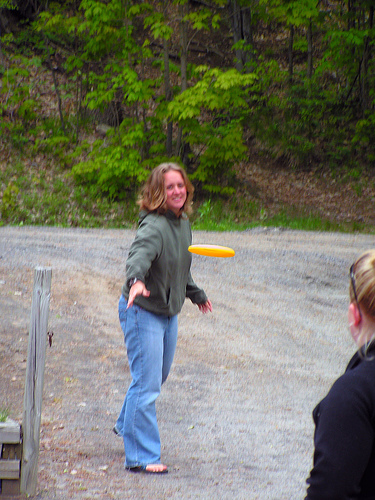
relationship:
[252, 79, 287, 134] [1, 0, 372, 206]
leaves on tree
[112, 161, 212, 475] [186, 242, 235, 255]
girl throwing a frisbee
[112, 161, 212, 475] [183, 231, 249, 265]
girl throwing a frisbee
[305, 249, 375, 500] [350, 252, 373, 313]
girl with hair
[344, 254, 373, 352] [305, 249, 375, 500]
head of a girl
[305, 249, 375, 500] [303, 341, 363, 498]
girl wearing a top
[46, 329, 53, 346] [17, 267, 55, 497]
key hanging from a fence post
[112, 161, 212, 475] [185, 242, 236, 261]
girl threw frisbee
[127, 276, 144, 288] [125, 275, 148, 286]
watch on wrist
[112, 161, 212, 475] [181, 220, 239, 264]
girl tossing frisbee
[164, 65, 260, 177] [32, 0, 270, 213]
leaves on tree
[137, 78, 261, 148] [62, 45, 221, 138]
leaves on tree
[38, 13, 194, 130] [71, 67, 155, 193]
leaves on tree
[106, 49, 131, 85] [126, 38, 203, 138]
green leaves on tree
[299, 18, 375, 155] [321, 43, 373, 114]
leaves on tree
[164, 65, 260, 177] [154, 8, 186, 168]
leaves on tree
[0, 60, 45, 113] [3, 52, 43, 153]
green leaves on tree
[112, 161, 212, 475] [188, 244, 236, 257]
girl threw flying disc